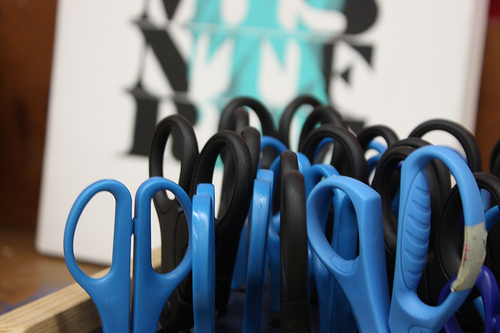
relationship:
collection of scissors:
[47, 160, 240, 330] [55, 173, 197, 329]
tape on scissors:
[443, 226, 497, 295] [273, 149, 313, 332]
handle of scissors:
[244, 162, 276, 294] [241, 169, 280, 304]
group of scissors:
[63, 92, 497, 331] [241, 169, 280, 304]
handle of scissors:
[452, 223, 490, 292] [451, 223, 482, 289]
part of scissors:
[190, 209, 214, 265] [451, 223, 482, 289]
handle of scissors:
[452, 223, 490, 292] [55, 173, 197, 329]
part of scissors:
[190, 209, 214, 265] [55, 173, 197, 329]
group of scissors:
[63, 92, 497, 331] [55, 173, 197, 329]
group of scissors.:
[63, 92, 497, 331] [58, 87, 495, 329]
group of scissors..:
[63, 92, 497, 331] [46, 81, 499, 330]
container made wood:
[3, 248, 164, 332] [3, 245, 165, 332]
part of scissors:
[190, 209, 214, 265] [49, 176, 243, 315]